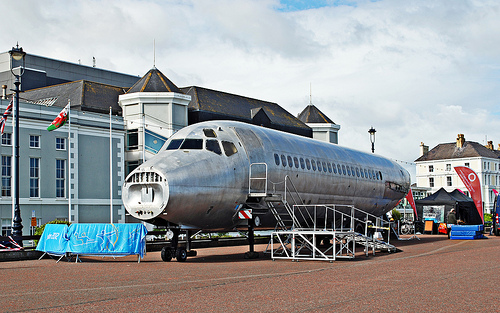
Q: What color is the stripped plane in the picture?
A: Gray.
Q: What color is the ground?
A: Red.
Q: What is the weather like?
A: Partly cloudy.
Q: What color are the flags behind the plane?
A: Red.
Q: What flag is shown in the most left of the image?
A: United Kingdom.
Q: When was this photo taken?
A: Day time.